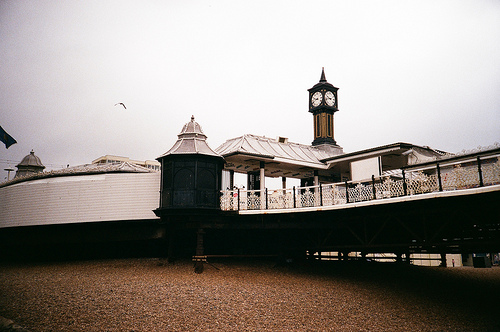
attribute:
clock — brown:
[310, 91, 324, 108]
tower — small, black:
[308, 63, 342, 145]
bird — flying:
[109, 102, 127, 110]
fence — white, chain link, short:
[221, 155, 500, 211]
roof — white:
[212, 136, 333, 179]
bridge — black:
[234, 186, 498, 257]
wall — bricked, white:
[5, 171, 166, 225]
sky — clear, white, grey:
[53, 36, 207, 97]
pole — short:
[236, 190, 243, 212]